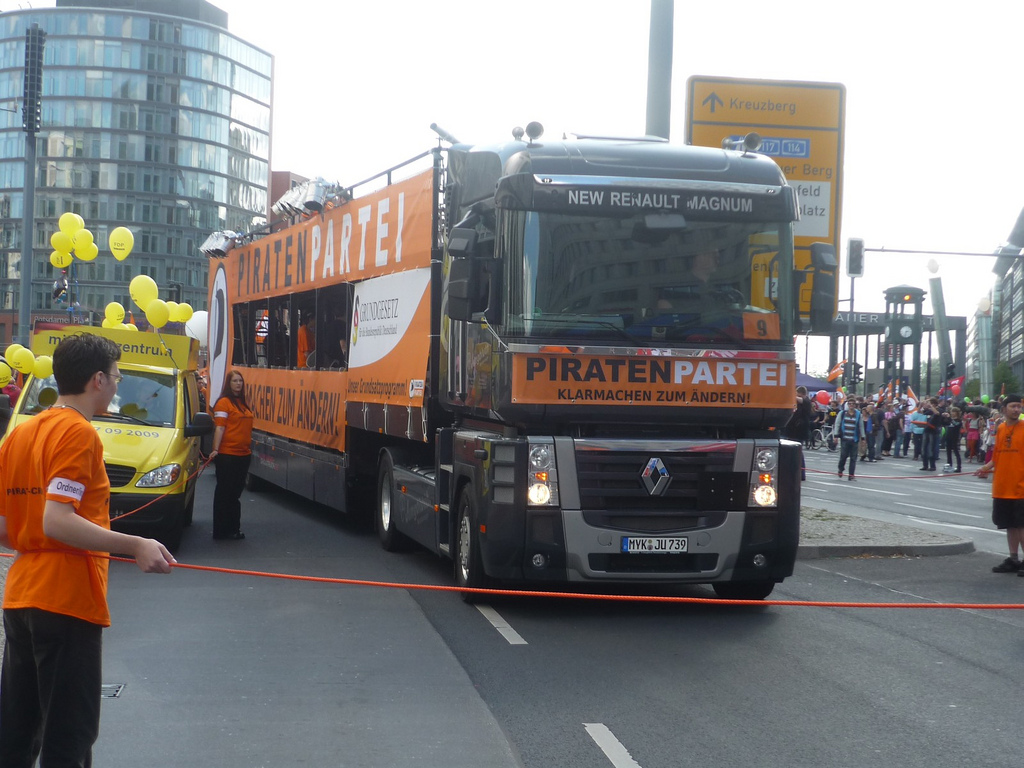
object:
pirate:
[526, 357, 647, 383]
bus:
[198, 122, 809, 605]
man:
[0, 334, 176, 768]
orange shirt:
[0, 406, 112, 628]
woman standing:
[210, 370, 256, 543]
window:
[504, 207, 794, 341]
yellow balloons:
[49, 250, 74, 267]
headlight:
[528, 443, 561, 507]